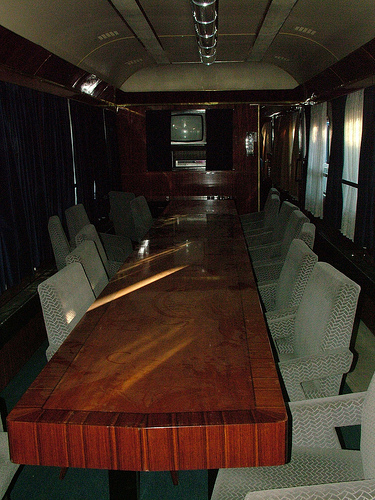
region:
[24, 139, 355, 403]
a brown wooden table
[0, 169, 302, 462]
a long conference table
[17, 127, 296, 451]
a wooden conference table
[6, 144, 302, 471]
a brown conference table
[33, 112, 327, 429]
a brown wooden conference table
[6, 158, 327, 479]
a long brown wooden table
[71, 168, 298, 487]
a conference table that is brown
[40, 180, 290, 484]
a conference table that is wooden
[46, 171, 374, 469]
chairs lining the table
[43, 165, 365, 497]
chairs lining the conference table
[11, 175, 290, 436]
a conference table in a train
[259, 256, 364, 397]
a chair at the table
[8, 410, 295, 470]
decorative end of the table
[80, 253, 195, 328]
reflection of light on the table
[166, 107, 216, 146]
old fashioned TV mounted high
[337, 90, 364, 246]
curtains on the window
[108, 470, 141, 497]
leg supporting the table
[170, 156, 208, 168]
electronic device in a stand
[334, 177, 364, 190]
a cross beam on the window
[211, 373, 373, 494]
a white chair in the corner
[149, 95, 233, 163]
television in the wall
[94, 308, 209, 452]
dust on the wood table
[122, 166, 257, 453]
long wood table with dust on it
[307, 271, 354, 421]
gray chairs with a pattern to it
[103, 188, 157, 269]
patterned gray chairs around a table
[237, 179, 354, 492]
chairs around a table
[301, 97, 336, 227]
sheer white curtains on the windows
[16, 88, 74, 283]
dark blue curtains on the windows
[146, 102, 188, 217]
black curtains covering the televison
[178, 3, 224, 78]
running lights above the desk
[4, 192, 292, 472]
Large wooden table in a train car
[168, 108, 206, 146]
Television in the train car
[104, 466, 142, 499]
Support post for large wooden table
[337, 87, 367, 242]
Window in the train car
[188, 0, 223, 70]
Overhead lighting in the train car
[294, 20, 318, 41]
Air vents in the train car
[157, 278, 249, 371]
Dusty tabletop and a train car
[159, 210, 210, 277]
Reflection on the tabletop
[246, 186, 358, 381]
Row of chairs at a table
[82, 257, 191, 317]
Sunlight beaming through the window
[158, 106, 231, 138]
television at the end of table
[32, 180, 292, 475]
extremely long wood table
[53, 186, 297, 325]
chairs on both sides of the table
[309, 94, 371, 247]
windows have curtains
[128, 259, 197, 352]
light on the table from windows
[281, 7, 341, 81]
ceiling is curved on top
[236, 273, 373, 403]
chairs have arms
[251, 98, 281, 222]
gold pole in front of table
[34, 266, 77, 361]
chair is push under table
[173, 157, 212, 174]
video player under the television